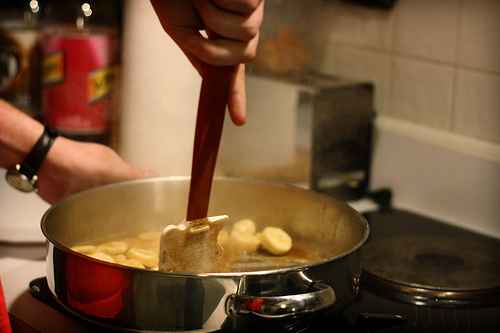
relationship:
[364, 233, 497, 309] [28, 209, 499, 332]
burner on stove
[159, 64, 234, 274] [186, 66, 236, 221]
spatula has handle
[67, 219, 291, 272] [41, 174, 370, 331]
banana in pan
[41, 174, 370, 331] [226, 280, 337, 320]
pan has handle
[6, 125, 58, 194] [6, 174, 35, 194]
watch has face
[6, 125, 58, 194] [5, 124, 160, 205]
watch on hand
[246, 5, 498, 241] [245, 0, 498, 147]
wall has tile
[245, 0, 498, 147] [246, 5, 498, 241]
tile on wall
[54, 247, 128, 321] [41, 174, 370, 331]
reflection on pan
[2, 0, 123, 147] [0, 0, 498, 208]
bottles in background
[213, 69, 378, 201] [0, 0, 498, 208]
toaster in background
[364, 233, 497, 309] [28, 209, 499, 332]
lid on stove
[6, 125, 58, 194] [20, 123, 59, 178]
watch has band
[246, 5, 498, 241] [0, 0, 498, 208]
wall in background